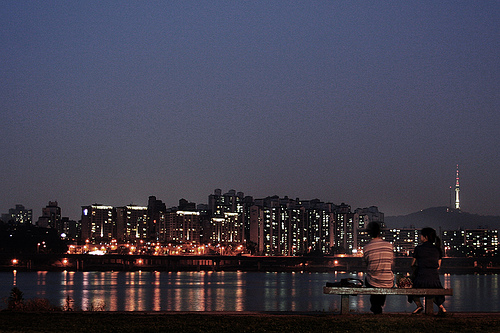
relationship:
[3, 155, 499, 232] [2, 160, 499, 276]
skyline of city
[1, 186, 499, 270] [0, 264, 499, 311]
city besides water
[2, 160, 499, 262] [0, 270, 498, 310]
lights on water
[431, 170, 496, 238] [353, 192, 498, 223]
tower on background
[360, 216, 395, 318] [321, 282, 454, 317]
man on bench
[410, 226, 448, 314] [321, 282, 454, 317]
person on bench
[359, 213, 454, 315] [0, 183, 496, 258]
couple look city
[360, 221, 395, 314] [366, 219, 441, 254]
man has dark hair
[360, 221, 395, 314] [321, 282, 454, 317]
man on bench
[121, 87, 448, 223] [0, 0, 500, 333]
time just after night